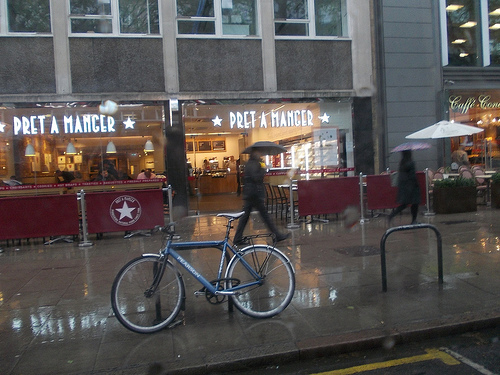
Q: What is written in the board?
A: Pret a manger.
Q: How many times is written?
A: 2.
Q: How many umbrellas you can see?
A: 3.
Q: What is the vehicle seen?
A: Cycle.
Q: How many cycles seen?
A: 1.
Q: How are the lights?
A: On.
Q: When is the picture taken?
A: Night time.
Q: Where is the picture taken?
A: On the sidewalk.